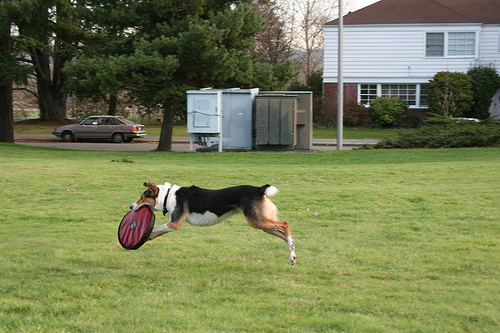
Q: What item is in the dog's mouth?
A: Frisbee.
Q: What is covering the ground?
A: Grass.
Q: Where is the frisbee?
A: In the dog's mouth.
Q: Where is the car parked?
A: On the road.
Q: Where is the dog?
A: On the grass.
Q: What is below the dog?
A: Grass.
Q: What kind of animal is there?
A: Dog.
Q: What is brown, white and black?
A: Dog.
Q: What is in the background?
A: A tree.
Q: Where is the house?
A: In the back of the photo.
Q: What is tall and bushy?
A: A green tree.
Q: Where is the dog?
A: Running outside.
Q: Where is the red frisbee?
A: In the dog's mouth.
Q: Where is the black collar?
A: On the dog's neck.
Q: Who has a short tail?
A: The dog.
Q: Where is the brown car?
A: In the background to the left of the dog.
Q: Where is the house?
A: In the background on the right side.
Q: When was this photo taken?
A: During the daytime.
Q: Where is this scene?
A: A park.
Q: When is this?
A: During the day.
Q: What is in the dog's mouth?
A: A Frisbee.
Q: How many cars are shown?
A: One.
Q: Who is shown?
A: A dog.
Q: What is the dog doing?
A: Running.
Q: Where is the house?
A: Across the street.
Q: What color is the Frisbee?
A: Black and red.